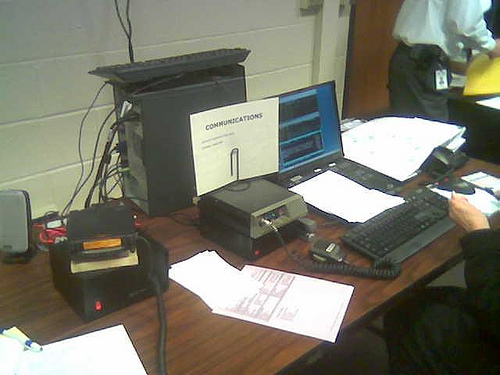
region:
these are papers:
[178, 246, 336, 340]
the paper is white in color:
[349, 115, 440, 174]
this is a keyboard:
[348, 192, 443, 264]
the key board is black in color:
[348, 178, 444, 265]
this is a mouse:
[436, 165, 473, 197]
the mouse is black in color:
[438, 172, 476, 197]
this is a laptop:
[263, 75, 407, 217]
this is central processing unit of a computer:
[111, 69, 248, 212]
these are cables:
[97, 81, 144, 198]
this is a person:
[378, 0, 497, 115]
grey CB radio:
[196, 175, 311, 245]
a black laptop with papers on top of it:
[259, 70, 401, 222]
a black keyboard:
[339, 185, 473, 280]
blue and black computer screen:
[262, 81, 344, 173]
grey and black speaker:
[0, 182, 35, 272]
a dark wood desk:
[1, 148, 498, 373]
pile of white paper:
[166, 246, 260, 317]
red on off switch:
[91, 296, 106, 319]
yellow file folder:
[457, 38, 499, 100]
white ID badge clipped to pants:
[431, 54, 455, 94]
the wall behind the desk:
[1, 1, 366, 184]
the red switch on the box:
[86, 294, 103, 317]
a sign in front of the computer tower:
[180, 95, 281, 195]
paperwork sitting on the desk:
[176, 246, 362, 357]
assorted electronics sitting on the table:
[0, 61, 468, 314]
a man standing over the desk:
[392, 2, 488, 134]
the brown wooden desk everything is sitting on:
[5, 118, 498, 364]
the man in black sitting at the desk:
[373, 195, 494, 360]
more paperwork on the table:
[341, 110, 492, 215]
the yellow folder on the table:
[463, 44, 498, 104]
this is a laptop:
[292, 84, 340, 164]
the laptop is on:
[288, 87, 331, 155]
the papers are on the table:
[205, 265, 338, 336]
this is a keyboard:
[405, 199, 437, 244]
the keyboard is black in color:
[403, 201, 442, 237]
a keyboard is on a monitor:
[135, 40, 250, 82]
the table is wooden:
[175, 337, 270, 368]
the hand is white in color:
[457, 208, 475, 223]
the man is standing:
[389, 3, 476, 100]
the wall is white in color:
[263, 18, 329, 80]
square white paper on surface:
[208, 268, 379, 351]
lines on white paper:
[228, 268, 305, 313]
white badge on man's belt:
[410, 63, 467, 103]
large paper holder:
[225, 145, 266, 202]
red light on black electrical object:
[70, 292, 117, 322]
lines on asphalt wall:
[0, 27, 81, 124]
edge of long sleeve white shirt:
[390, 19, 494, 70]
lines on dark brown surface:
[180, 323, 240, 369]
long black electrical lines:
[74, 70, 134, 178]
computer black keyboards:
[335, 200, 458, 276]